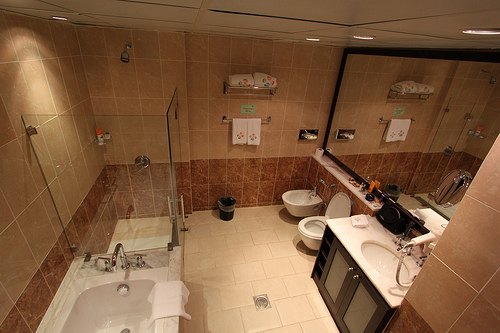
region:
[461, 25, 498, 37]
A light in the ceiling.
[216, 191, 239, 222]
A black garbage can.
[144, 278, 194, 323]
A towel on the tub.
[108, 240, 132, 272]
A faucet on the tub.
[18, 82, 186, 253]
A clear walk in shower.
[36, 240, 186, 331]
A white marble tub.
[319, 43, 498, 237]
A long bathroom mirror.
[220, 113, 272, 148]
Towels hanging on the wall.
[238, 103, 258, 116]
A sign on the wall.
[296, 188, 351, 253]
A toilet with the seat up.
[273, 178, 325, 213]
badet in the corner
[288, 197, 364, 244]
toilet next to badet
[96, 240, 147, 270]
valves on the bathtub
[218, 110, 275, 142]
towel rack on the wall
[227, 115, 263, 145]
towels on the rack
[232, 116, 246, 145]
towel on the rack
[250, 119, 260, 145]
towell on the rack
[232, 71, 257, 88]
towel on the shelf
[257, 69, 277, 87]
towel on the shelf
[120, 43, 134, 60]
shower head on the wall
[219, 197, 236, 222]
The black trash can.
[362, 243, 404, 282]
The basin of the sink.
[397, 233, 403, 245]
The left knob on the sink.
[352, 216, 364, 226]
The small wash cloth on the sink counter.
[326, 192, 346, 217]
The lid of the toilet.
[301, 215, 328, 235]
The seat of the toilet.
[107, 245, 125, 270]
The faucet of the tub.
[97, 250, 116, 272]
The left knob to turn the bath water on.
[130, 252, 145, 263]
The right knob to turn the bath water on.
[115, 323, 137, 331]
The drain hole in the tub.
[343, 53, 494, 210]
huge mirror is on the wall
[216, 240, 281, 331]
the floor has white tiles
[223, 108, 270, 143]
towels are white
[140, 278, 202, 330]
the towel is on the bathtub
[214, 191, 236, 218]
the trush can is black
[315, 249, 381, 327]
the cabinet doors are closed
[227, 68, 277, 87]
towels are on the rack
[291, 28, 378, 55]
the light is on the ceiling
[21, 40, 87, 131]
light reflection is on the wall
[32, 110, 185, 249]
the shower doors are made of glass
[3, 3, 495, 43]
recessed lights in ceiling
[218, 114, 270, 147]
two towels in racks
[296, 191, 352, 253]
toilet with open cover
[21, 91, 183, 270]
glass wall of shower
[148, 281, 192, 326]
towel on edge of tub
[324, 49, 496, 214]
reflection in bathroom mirror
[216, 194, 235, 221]
plastic bag in can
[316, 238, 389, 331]
two doors of vanity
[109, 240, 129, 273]
curved faucet over tub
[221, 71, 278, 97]
two rolled towels on shelf